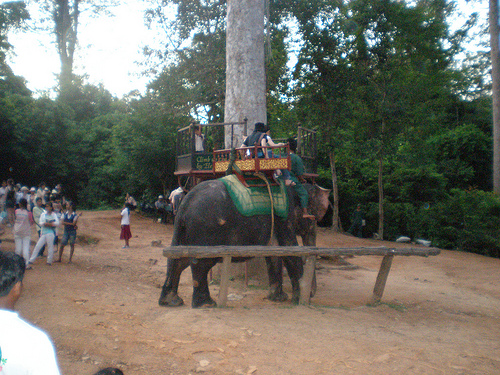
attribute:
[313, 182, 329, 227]
ear — pink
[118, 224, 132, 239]
skirt — red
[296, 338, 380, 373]
dirt — brown, small patch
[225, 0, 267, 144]
trunk — brown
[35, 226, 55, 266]
pants — white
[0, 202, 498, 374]
brown dirt — small patch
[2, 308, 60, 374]
shirt — white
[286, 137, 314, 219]
person — dressed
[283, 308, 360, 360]
ground — wooden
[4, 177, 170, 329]
people — standing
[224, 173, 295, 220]
rug — green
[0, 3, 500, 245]
trees — green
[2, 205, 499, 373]
dirt — small patch, brown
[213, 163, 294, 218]
blanket — green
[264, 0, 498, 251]
tree — leafy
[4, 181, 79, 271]
people — many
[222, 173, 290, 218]
pad — green, beige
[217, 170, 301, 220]
cushion — green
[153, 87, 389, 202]
3 people — riding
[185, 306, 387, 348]
dirt — brown, small patch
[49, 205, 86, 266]
girl — wearing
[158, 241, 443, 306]
post — large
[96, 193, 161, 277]
shirt — red